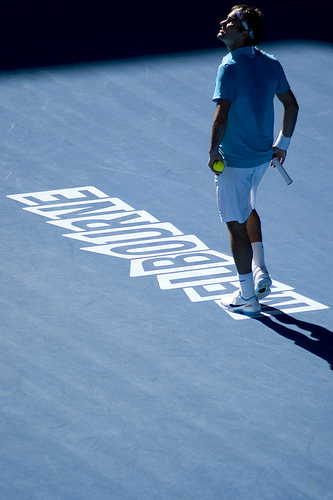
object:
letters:
[5, 186, 330, 321]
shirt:
[212, 44, 292, 170]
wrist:
[209, 141, 218, 155]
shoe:
[253, 265, 272, 300]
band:
[275, 129, 292, 150]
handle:
[272, 157, 293, 186]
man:
[207, 4, 299, 318]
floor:
[0, 48, 332, 497]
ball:
[213, 161, 225, 173]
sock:
[239, 280, 245, 283]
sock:
[261, 245, 264, 248]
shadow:
[258, 304, 333, 372]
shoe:
[220, 288, 261, 318]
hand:
[269, 144, 287, 169]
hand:
[208, 152, 224, 177]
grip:
[273, 155, 293, 185]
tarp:
[0, 37, 332, 496]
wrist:
[277, 133, 289, 148]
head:
[217, 4, 263, 47]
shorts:
[214, 159, 271, 224]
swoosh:
[229, 303, 245, 307]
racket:
[272, 156, 293, 186]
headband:
[233, 8, 254, 39]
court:
[0, 43, 333, 498]